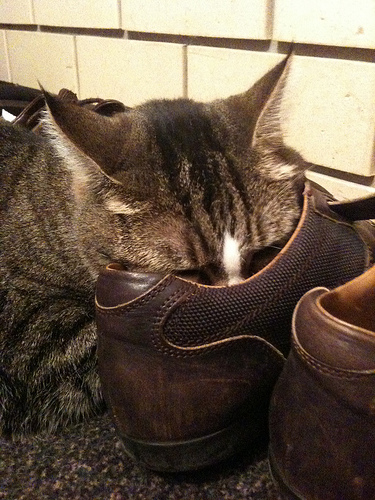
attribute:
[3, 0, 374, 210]
wall — tiled, black, white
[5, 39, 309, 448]
cat — sniffing, tabby, sitting, tan, sleeping, brown, black, snoozing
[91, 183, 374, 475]
shoe — brown, leather, mans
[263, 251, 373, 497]
shoe — leather, brown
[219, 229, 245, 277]
mark — white, furry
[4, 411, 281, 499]
rug — brown, gray, dark brown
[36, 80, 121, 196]
ear — pointy, hairy, fluffy, fuzzy, brown, furry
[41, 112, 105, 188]
hair — white, fluffy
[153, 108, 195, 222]
stripe — dark, black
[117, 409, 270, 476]
sole — black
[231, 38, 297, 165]
ear — pointy, hairy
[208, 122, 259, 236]
stripe — black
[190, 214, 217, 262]
stripe — black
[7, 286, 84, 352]
stripe — black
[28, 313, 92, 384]
stripe — black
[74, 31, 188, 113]
tile — rectangular, white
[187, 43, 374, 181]
tile — rectangular, white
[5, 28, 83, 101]
tile — rectangular, white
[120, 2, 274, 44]
tile — white, rectangular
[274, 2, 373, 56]
tile — rectangular, white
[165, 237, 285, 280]
eyes — sleepy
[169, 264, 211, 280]
eye — sleepy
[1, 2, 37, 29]
block — white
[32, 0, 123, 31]
block — white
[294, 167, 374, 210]
block — white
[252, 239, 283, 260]
eye — sleepy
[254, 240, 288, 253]
eyebrow whisker — folded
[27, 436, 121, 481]
yarns — earth tone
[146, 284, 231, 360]
seam — double, shaped, question mark shape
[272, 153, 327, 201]
eyebrow whisker — pointing up